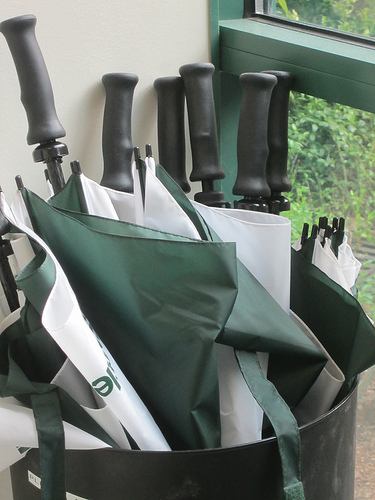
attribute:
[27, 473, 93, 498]
label — white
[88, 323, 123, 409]
lettering — green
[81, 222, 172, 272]
umbrella — green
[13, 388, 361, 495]
barrel — black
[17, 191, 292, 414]
umbrellas — white, green 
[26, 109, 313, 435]
umbrella — grouped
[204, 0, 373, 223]
window frame — green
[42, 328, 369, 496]
garbage — black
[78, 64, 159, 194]
handle — black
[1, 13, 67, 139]
handle — black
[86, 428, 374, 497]
bin — black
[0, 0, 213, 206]
wall — white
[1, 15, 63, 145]
handle — black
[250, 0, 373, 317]
window — green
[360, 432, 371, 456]
ground — brown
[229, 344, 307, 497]
string — green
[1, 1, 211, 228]
wall — white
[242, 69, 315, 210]
handles — black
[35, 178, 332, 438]
umbrellas — green, white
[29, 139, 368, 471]
umbrellas — green and white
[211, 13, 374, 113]
sill — green